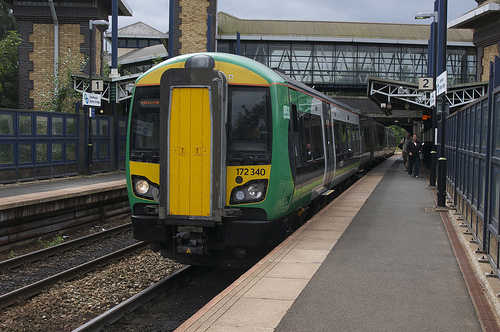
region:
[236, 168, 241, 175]
a number '1' written in black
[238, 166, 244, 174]
a number '7' written in black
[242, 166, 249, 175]
a number '2' written in black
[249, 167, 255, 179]
a number '3' written in black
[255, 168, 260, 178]
a number '4' written in black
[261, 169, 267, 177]
a number '0' written in black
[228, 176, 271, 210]
a light on a train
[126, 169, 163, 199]
a light on a train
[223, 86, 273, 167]
a window on a train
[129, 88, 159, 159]
a window on a train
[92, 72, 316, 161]
this is a train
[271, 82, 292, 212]
the train is green in color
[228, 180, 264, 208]
the front light is off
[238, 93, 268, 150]
this is the front screen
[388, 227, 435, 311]
this is a pavement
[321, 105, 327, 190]
the door is closed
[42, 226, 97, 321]
this is a railway line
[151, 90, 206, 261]
this is yellow in color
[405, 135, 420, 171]
this is a man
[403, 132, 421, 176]
the man is walking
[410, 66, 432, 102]
Black number 2 on sign.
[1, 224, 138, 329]
Rail road tracks and gravel.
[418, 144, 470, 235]
Black pole in cement.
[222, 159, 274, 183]
Black numbers that are 172 340.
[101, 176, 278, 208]
Head lights on front of train.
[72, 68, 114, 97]
Black number 1 on sign.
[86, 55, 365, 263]
Green yellow and black train.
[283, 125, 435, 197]
People standing by a train.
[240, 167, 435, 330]
Side walk next to train.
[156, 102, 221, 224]
Yellow door on front of train.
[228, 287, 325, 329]
tiles on the platform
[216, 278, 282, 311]
small lines in the tiles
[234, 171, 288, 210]
silver light on front of train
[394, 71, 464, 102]
small white sign on post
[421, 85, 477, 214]
shiny black post on side of platform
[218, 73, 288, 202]
black window in train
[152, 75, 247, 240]
yellow door on front of train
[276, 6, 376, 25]
dark clouds in the sky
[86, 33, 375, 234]
large green and yellow train on track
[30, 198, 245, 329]
long black train tracks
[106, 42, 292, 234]
The front of the train is yellow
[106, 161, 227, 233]
The lights are off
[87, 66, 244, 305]
The train is not moving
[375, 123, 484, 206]
The people are walking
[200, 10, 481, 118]
There is a bridge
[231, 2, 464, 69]
The sky is cloudy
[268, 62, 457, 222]
The train has windows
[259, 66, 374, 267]
The train is green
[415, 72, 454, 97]
This is the number 2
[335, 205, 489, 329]
The sidewalk is gray